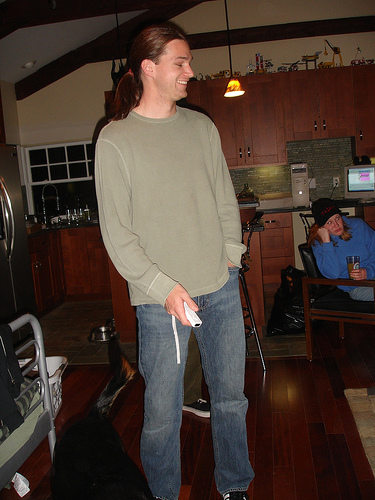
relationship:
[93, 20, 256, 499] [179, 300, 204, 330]
man playing wii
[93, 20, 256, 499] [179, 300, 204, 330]
man plays wii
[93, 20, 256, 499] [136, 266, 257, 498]
man wears jeans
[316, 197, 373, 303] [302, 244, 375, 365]
person in chair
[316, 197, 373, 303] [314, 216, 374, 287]
person wears sweatshirt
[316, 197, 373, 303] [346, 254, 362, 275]
person holding cup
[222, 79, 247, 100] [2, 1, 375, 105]
light hangs from ceiling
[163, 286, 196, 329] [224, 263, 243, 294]
hand in pocket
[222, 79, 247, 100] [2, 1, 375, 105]
light hanging from ceiling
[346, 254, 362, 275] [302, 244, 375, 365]
cup on chair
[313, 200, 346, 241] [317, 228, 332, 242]
head in a hand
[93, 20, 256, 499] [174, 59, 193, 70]
man closed eyes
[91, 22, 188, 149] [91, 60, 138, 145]
hair in a ponytail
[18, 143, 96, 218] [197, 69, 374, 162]
window near cabinets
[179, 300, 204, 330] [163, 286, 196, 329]
wii in hand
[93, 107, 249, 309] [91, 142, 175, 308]
shirt has long sleeves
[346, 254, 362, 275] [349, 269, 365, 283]
cup in hand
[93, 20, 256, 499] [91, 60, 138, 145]
man wears ponytail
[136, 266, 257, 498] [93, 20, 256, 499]
jeans on man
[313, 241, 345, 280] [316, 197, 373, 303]
sleeve on person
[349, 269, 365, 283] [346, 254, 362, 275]
hand holding cup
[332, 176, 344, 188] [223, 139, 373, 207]
outlet on wall